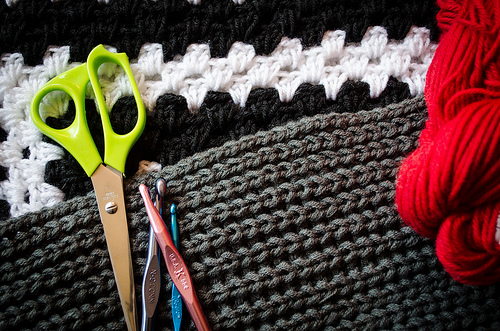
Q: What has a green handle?
A: Scissors.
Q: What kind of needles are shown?
A: Knitting needles.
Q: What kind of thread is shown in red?
A: Yarn.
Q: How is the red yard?
A: In a bundle.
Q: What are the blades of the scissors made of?
A: Metal.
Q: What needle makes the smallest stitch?
A: The blue needle.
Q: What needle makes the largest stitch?
A: The grey needle.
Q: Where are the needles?
A: On top of grey fabric.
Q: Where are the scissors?
A: On the scarf.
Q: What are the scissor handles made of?
A: Plastic.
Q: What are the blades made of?
A: Metal.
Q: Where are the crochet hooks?
A: Next to the scissors.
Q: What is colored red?
A: A roll of yarn.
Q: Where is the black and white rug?
A: Under the gray scarf.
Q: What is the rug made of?
A: Crochet yarn.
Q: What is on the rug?
A: A scarf.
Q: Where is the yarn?
A: On the right side of the scarf.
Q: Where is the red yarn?
A: On the right side.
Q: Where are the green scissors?
A: Next to the crochet hooks.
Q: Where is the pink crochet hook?
A: On top of the blue and purple hooks.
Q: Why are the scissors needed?
A: To cut the yarn.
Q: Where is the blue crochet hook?
A: Under the pink hook.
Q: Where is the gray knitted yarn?
A: Underneath the scissors and the hooks.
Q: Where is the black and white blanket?
A: Underneath all of the items.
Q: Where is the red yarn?
A: On top of the gray blanket.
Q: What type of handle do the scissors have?
A: A green handle.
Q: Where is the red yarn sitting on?
A: A woolen scarf.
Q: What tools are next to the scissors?
A: Three tools for the crochet.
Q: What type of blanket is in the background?
A: A black and white blanket.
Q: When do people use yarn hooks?
A: When they crochet.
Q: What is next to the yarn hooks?
A: Scissors.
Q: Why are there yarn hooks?
A: Someone was using them.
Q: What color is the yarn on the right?
A: Red.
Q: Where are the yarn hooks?
A: Next to the scissors.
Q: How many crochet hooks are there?
A: 3.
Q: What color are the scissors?
A: Green.